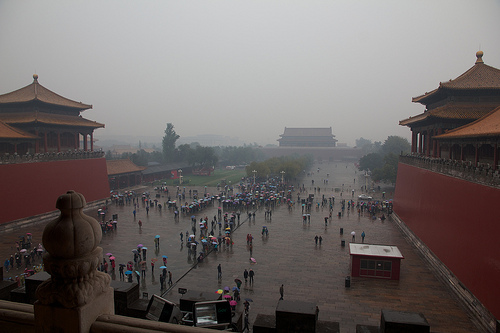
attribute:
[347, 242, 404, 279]
building — red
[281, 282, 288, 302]
shirt — blue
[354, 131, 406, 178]
leaves — green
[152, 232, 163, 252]
boy — riding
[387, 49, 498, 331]
building — red, brown, large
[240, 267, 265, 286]
person — standing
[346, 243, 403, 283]
room — small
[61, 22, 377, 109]
clouds — white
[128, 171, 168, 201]
boy — riding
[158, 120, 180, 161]
tree — long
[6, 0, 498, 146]
clouds — white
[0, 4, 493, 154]
sky — gray, foggy, blue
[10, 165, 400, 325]
people — walking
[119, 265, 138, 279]
boy — riding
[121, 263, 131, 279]
shirt — blue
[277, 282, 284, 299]
boy — riding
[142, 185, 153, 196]
shirt — blue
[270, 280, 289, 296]
shirt — blue 